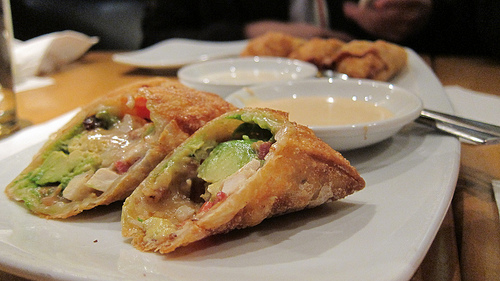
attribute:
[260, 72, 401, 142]
bowl — shallow, white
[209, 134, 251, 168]
avacado — green, spicy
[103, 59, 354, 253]
food — fried, prepared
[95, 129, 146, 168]
chicken — bits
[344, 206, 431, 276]
plate — square, white, large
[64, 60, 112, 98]
table — put together, wooden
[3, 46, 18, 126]
water — filled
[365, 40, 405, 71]
bread — fried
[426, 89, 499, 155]
utensil — metal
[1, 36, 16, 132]
glass — clear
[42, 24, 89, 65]
napkin — white